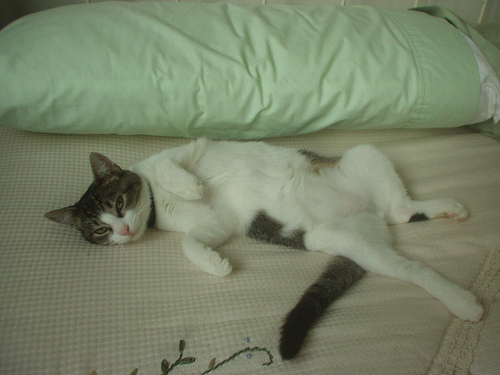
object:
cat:
[42, 133, 483, 361]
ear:
[90, 151, 117, 178]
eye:
[115, 192, 128, 213]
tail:
[273, 254, 362, 365]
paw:
[181, 174, 203, 201]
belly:
[208, 141, 358, 253]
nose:
[116, 221, 131, 236]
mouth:
[131, 225, 140, 240]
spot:
[245, 208, 305, 250]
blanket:
[0, 132, 498, 374]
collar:
[138, 166, 159, 229]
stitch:
[90, 339, 273, 374]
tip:
[275, 331, 302, 361]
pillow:
[0, 0, 500, 139]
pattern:
[442, 135, 468, 166]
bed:
[0, 0, 499, 374]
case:
[0, 0, 499, 139]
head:
[45, 148, 155, 246]